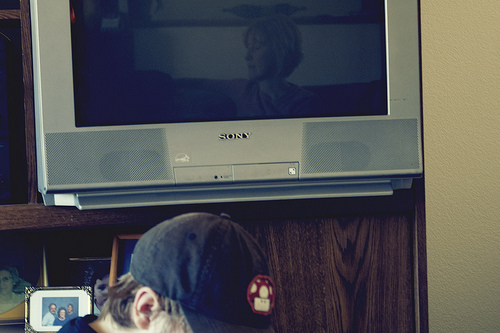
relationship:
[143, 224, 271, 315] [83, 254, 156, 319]
hat on person